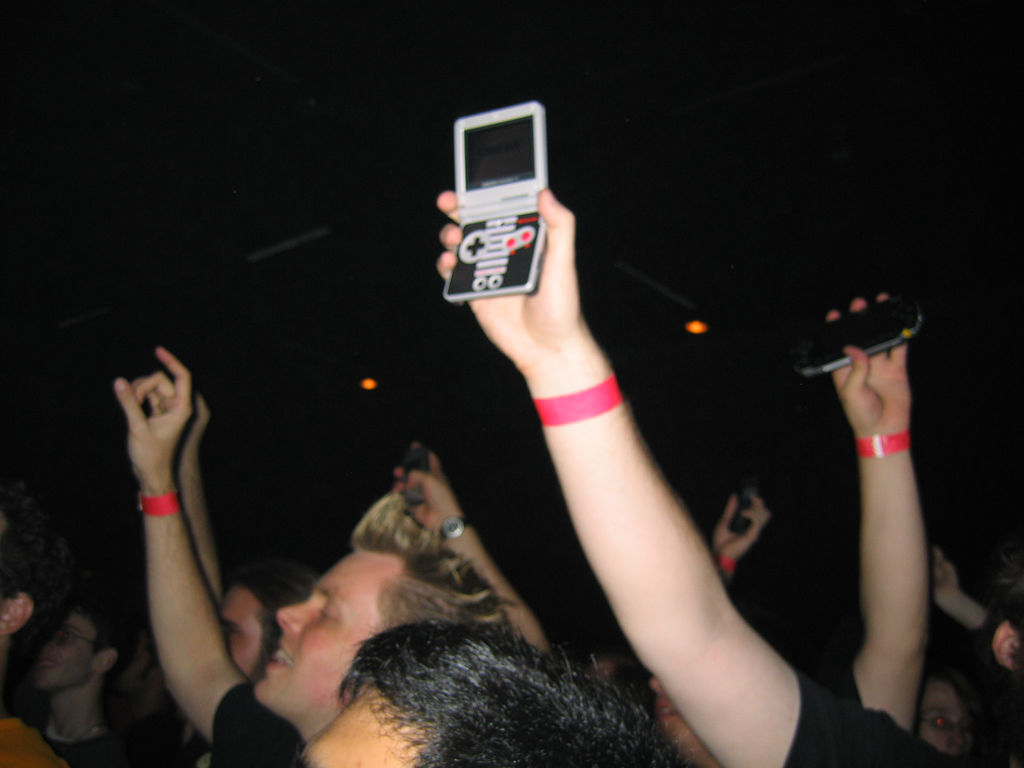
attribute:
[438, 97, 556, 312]
nintendo — small, ds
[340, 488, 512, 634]
hair — bleached blonde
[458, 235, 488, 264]
pad — black